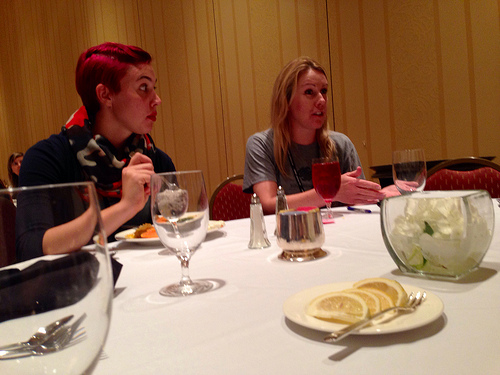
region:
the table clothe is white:
[143, 332, 308, 374]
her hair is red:
[62, 33, 164, 77]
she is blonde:
[223, 55, 385, 211]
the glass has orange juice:
[302, 142, 364, 210]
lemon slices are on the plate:
[280, 258, 475, 352]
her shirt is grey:
[243, 140, 381, 185]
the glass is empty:
[9, 182, 123, 371]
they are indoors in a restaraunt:
[4, 10, 490, 360]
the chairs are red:
[422, 150, 499, 187]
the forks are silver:
[9, 315, 85, 363]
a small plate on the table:
[271, 256, 454, 336]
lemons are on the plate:
[275, 265, 431, 345]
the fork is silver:
[320, 280, 440, 345]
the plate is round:
[270, 256, 445, 336]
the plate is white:
[237, 272, 447, 343]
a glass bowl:
[357, 180, 487, 285]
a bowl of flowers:
[353, 171, 487, 301]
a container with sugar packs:
[258, 197, 337, 258]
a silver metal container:
[269, 188, 324, 268]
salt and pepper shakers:
[228, 177, 298, 252]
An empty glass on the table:
[141, 165, 226, 305]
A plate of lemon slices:
[282, 270, 449, 346]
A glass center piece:
[375, 180, 496, 282]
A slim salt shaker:
[244, 187, 271, 254]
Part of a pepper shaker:
[269, 179, 291, 225]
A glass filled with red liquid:
[306, 150, 348, 227]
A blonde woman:
[240, 55, 422, 207]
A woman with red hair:
[14, 37, 192, 259]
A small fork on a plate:
[322, 288, 432, 356]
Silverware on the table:
[0, 307, 100, 363]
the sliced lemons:
[313, 279, 401, 322]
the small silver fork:
[324, 285, 423, 351]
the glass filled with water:
[147, 174, 212, 292]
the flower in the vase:
[381, 178, 495, 283]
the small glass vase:
[378, 181, 490, 276]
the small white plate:
[287, 272, 442, 341]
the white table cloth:
[154, 304, 239, 374]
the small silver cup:
[274, 202, 326, 259]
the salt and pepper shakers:
[247, 182, 294, 252]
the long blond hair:
[269, 47, 335, 177]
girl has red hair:
[72, 29, 171, 83]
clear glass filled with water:
[122, 157, 218, 319]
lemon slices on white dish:
[307, 268, 412, 320]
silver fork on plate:
[330, 278, 436, 333]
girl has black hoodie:
[32, 122, 191, 225]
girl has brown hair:
[265, 55, 335, 147]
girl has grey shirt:
[229, 126, 381, 211]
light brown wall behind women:
[122, 6, 292, 123]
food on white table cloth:
[151, 228, 306, 373]